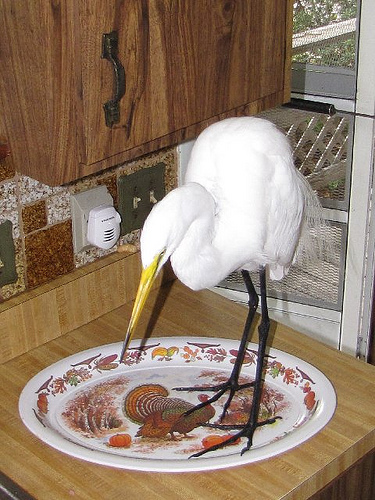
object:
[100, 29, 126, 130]
handle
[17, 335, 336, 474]
plate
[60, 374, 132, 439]
pattern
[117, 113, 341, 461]
crane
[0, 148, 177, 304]
tiles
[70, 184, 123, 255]
plug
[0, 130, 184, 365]
wall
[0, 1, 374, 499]
room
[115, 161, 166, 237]
light panel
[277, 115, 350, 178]
lattice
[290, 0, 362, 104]
patio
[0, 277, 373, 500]
countertop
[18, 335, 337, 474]
treats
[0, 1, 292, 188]
cabinet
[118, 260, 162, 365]
beak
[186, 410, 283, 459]
feet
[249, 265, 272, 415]
legs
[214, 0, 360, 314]
screen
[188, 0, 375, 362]
door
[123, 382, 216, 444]
turkey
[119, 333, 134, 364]
tip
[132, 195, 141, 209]
switch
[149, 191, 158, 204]
switch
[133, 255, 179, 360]
shadow